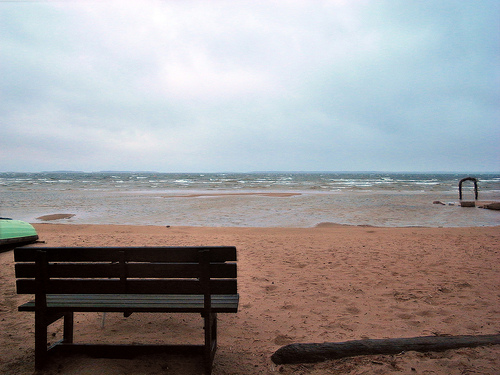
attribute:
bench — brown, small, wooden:
[9, 238, 241, 368]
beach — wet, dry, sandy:
[3, 220, 500, 375]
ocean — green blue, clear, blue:
[3, 166, 500, 194]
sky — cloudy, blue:
[1, 0, 499, 175]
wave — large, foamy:
[314, 175, 448, 188]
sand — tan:
[0, 223, 499, 373]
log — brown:
[268, 331, 499, 375]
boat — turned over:
[0, 214, 42, 255]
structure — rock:
[451, 177, 499, 211]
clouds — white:
[0, 0, 499, 176]